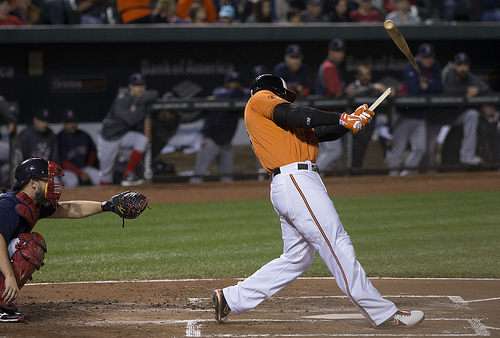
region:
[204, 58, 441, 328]
the batter on the field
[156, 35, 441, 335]
the batter swinging the bat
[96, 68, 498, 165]
players in the dugout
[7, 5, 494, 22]
spectators in the stands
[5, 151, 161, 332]
catcher behind the batter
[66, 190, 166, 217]
the arm is outstretched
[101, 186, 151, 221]
the mitt of the catcher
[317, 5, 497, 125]
the bat is broken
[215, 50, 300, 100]
the helmet of the player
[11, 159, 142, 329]
the catcher is crouched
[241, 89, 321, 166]
Man wearing orange shirt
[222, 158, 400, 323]
White pants with an orange stripe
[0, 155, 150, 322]
Umpire at a baseball game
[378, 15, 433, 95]
Baseball bat in the air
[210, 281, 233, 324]
Black and orange tennis shoe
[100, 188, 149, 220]
Black and red catchers mit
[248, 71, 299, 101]
Man wearing a black hat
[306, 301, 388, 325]
Home plate on baseball field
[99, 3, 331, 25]
Several people in a crowd at baseball game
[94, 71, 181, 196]
Man leaning on a fence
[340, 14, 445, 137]
broken baseball bat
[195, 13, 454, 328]
baseball player in a baseball field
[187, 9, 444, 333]
baseball player that broke his bat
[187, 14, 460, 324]
baseball player wearing an orange shirt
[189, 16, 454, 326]
baseball player wearing white pants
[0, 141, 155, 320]
umpire crouching down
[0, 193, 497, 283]
green turf grass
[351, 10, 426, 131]
broken bat flying through the air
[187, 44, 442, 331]
baseball player wearing black hat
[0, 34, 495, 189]
baseball players watching the game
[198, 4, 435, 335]
guy playing baseball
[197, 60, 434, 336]
guy wearing a orange shirt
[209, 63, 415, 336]
guy wearing a black helmet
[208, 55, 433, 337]
guy wearing orange and white gloves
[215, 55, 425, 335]
guy wearing white pants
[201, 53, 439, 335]
guy wearing tennis shoes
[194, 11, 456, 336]
guy breaks baseball bat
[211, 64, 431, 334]
guy holding half of a baseball bat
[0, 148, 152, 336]
guy wearing a face mask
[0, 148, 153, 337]
guy left arm extended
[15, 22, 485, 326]
professional baseball game in progress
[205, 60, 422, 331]
batter at professional game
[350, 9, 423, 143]
baseball bat being broke by force of swing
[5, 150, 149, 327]
professional catcher at baseball game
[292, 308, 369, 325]
home plate for baseball game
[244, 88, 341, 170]
orange and black long sleeved shirt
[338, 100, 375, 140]
orange and white batting gloves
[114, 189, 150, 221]
black and red baseball mitt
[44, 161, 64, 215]
red face mask for protection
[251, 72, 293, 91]
black batters helmet